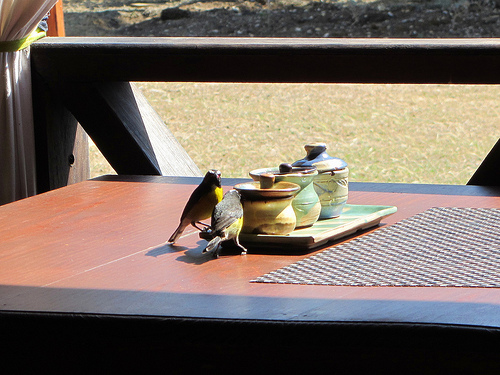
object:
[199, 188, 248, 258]
birds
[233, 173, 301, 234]
jars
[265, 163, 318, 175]
lids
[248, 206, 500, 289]
mat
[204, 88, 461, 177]
grass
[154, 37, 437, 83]
rail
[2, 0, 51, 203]
curtain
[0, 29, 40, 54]
tie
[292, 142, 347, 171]
lid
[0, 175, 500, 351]
table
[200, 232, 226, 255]
tail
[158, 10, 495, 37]
trees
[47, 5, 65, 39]
frame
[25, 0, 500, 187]
window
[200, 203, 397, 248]
platter